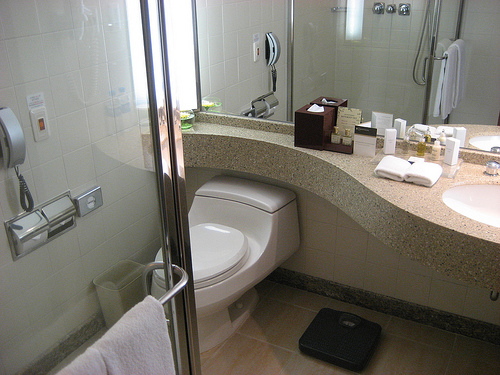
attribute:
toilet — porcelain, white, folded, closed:
[148, 174, 302, 353]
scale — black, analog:
[297, 306, 382, 371]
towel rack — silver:
[157, 265, 190, 306]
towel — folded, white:
[93, 294, 177, 374]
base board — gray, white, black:
[265, 265, 500, 345]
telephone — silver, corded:
[0, 105, 34, 214]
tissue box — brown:
[293, 101, 335, 151]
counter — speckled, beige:
[142, 120, 499, 292]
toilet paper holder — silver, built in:
[4, 189, 77, 263]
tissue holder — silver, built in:
[75, 186, 105, 219]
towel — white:
[53, 347, 110, 375]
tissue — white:
[306, 102, 325, 113]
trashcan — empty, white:
[93, 259, 148, 331]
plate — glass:
[369, 144, 464, 180]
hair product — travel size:
[429, 140, 440, 163]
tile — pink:
[201, 330, 295, 375]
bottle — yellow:
[416, 136, 426, 157]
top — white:
[419, 137, 425, 144]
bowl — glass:
[179, 105, 195, 130]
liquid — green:
[181, 114, 196, 130]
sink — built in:
[441, 182, 499, 230]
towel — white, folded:
[405, 161, 443, 188]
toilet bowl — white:
[153, 222, 251, 292]